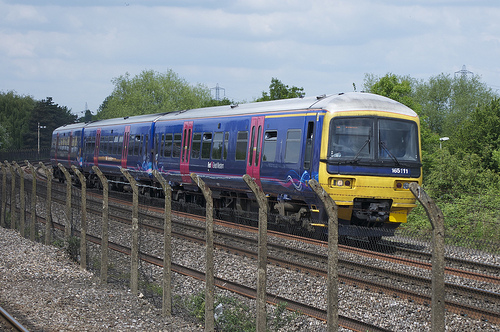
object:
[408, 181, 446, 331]
poles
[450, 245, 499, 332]
fencing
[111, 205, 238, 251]
tracks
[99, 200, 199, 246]
side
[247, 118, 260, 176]
doors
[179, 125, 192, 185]
doors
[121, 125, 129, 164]
doors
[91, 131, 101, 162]
doors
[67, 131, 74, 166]
doors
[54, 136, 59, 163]
doors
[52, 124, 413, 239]
train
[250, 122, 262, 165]
windows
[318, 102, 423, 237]
front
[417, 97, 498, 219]
trees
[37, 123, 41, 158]
pole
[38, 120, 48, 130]
sign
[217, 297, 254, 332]
plants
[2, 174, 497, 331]
fence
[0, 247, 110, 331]
gravel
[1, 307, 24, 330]
rails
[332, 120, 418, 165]
windows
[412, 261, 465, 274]
tracks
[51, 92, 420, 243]
cars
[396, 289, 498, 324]
sets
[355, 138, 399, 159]
wipers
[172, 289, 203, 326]
weeds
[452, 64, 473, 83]
tower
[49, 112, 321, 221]
side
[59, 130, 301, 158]
window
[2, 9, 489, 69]
sky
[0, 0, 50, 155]
background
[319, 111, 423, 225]
yellow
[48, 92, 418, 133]
roof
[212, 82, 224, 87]
top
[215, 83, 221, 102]
pole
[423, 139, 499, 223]
bushes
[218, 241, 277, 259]
track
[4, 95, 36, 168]
trees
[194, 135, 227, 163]
windows